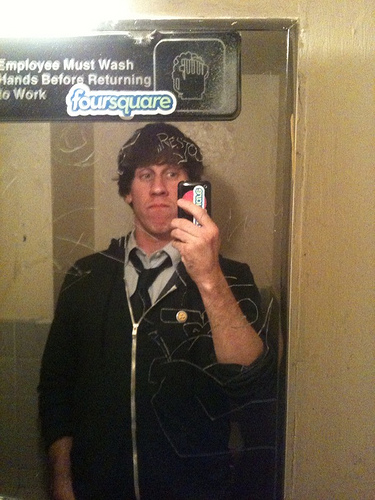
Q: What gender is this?
A: Male.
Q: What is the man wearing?
A: Hoodie.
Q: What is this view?
A: Mirror.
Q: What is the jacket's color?
A: Black.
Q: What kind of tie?
A: Long.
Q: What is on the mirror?
A: Writing.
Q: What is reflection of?
A: A man.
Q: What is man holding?
A: Cellphone.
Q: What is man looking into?
A: Mirror.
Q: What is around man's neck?
A: Tie.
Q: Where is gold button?
A: On jacket.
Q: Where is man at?
A: Bathroom.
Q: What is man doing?
A: Taking a picture.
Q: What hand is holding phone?
A: Left.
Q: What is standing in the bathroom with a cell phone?
A: The man.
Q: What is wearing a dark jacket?
A: The man.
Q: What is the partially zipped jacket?
A: Dark.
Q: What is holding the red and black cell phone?
A: The hand.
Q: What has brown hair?
A: The person.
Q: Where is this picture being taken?
A: Bathroom.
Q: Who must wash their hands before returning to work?
A: Employees.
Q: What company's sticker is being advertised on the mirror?
A: Foursquare.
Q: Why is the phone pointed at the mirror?
A: To take a picture.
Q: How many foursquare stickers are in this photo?
A: Two.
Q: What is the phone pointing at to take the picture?
A: A mirror.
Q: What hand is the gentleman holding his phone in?
A: Left hand.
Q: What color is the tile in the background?
A: Gray.